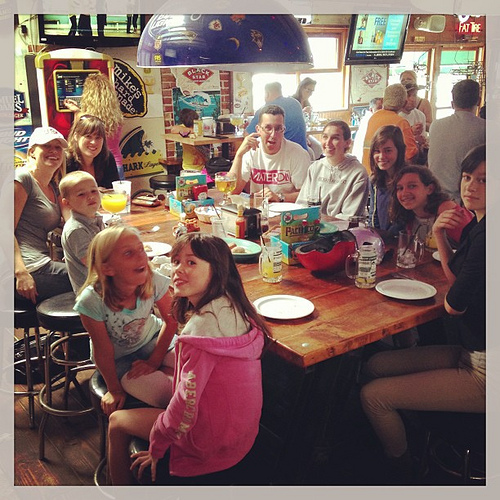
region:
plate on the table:
[245, 283, 333, 340]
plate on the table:
[364, 259, 448, 328]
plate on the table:
[120, 221, 193, 280]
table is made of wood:
[273, 295, 364, 413]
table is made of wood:
[250, 243, 412, 368]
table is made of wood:
[115, 188, 192, 230]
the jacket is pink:
[128, 270, 263, 497]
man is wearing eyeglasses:
[240, 98, 288, 172]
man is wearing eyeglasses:
[245, 109, 307, 160]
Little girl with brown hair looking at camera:
[157, 231, 279, 359]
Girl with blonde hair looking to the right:
[80, 221, 162, 325]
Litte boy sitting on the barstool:
[48, 165, 122, 286]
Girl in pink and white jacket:
[153, 243, 285, 477]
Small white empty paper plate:
[369, 264, 444, 317]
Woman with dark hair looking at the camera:
[440, 138, 499, 253]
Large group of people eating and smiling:
[14, 14, 496, 499]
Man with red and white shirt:
[216, 99, 311, 210]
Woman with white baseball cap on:
[22, 121, 73, 177]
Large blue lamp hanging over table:
[117, 13, 320, 95]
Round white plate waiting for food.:
[243, 290, 319, 330]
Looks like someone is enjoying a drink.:
[87, 189, 136, 223]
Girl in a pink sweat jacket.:
[133, 209, 266, 482]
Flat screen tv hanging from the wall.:
[341, 17, 415, 69]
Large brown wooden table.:
[325, 293, 357, 348]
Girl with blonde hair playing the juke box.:
[72, 68, 127, 167]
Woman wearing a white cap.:
[24, 117, 78, 156]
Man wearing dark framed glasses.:
[251, 108, 294, 144]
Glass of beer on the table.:
[211, 168, 246, 199]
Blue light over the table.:
[119, 18, 321, 78]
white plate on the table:
[256, 290, 314, 322]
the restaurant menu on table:
[275, 211, 319, 236]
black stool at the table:
[37, 295, 80, 463]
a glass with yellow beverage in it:
[257, 238, 287, 280]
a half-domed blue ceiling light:
[140, 10, 310, 69]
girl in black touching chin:
[437, 139, 494, 304]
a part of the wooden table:
[331, 290, 376, 326]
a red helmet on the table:
[301, 236, 353, 271]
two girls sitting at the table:
[82, 232, 260, 474]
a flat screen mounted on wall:
[350, 12, 405, 63]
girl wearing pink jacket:
[122, 218, 288, 498]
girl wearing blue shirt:
[53, 224, 203, 386]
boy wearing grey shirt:
[44, 182, 132, 315]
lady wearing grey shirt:
[15, 160, 82, 313]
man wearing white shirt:
[225, 108, 307, 218]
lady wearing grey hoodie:
[289, 121, 382, 229]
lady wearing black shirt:
[435, 206, 499, 364]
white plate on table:
[232, 277, 323, 346]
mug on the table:
[335, 230, 398, 313]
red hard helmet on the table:
[287, 225, 384, 290]